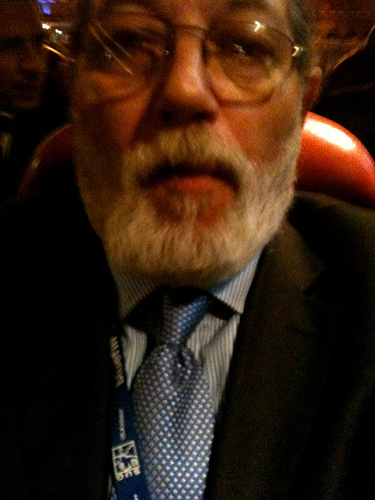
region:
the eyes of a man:
[79, 13, 315, 128]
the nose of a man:
[145, 63, 237, 120]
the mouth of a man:
[125, 142, 265, 202]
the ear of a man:
[264, 45, 341, 156]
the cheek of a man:
[71, 74, 176, 183]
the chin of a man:
[106, 206, 267, 320]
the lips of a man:
[127, 129, 257, 216]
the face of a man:
[90, 3, 332, 313]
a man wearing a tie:
[71, 100, 353, 468]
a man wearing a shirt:
[41, 75, 371, 438]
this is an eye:
[90, 12, 177, 83]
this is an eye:
[220, 31, 268, 76]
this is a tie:
[143, 280, 204, 480]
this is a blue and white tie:
[147, 301, 220, 492]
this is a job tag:
[111, 425, 138, 496]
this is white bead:
[202, 232, 244, 259]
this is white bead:
[241, 182, 266, 225]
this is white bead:
[110, 179, 137, 245]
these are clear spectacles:
[86, 7, 275, 76]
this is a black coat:
[278, 356, 327, 414]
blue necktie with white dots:
[129, 297, 213, 499]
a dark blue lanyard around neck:
[98, 305, 147, 497]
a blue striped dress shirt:
[111, 251, 264, 412]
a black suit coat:
[1, 190, 369, 493]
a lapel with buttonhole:
[227, 208, 344, 496]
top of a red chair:
[16, 109, 370, 196]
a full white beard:
[67, 97, 302, 273]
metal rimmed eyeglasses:
[64, 8, 307, 103]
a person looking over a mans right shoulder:
[0, 2, 55, 114]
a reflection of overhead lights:
[77, 22, 137, 83]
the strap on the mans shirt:
[103, 323, 148, 499]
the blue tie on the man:
[137, 296, 224, 498]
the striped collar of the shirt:
[207, 280, 247, 317]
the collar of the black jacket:
[253, 233, 323, 336]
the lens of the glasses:
[211, 24, 294, 91]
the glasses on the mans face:
[62, 8, 306, 95]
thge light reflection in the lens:
[244, 15, 270, 38]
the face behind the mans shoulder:
[1, 0, 61, 118]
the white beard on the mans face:
[70, 107, 298, 293]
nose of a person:
[147, 26, 237, 129]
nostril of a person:
[153, 101, 174, 131]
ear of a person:
[301, 47, 323, 137]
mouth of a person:
[135, 131, 232, 200]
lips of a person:
[130, 144, 246, 197]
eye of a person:
[80, 26, 159, 56]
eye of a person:
[226, 15, 276, 62]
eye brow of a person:
[213, 2, 290, 26]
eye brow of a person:
[101, 5, 172, 36]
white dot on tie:
[196, 487, 201, 496]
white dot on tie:
[188, 488, 199, 496]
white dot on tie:
[172, 486, 181, 493]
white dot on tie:
[155, 483, 164, 495]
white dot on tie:
[143, 457, 149, 466]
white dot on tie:
[144, 421, 150, 427]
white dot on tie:
[151, 425, 159, 434]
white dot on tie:
[193, 398, 199, 405]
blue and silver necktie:
[120, 289, 220, 499]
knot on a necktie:
[142, 289, 207, 352]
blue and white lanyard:
[87, 262, 148, 498]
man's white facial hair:
[65, 105, 305, 293]